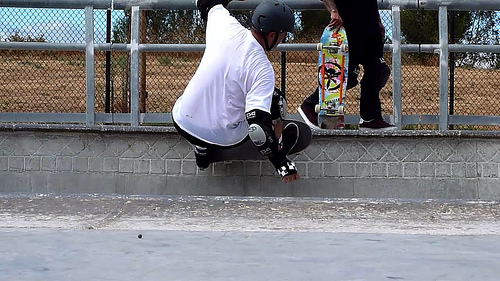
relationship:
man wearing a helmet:
[172, 0, 301, 183] [252, 0, 295, 51]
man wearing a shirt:
[172, 0, 301, 183] [172, 4, 275, 146]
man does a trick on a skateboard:
[172, 0, 301, 183] [209, 119, 312, 164]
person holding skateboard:
[297, 0, 391, 131] [314, 24, 349, 129]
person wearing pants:
[297, 0, 391, 131] [304, 29, 384, 118]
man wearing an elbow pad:
[172, 0, 301, 183] [245, 109, 279, 156]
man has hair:
[172, 0, 301, 183] [250, 26, 271, 38]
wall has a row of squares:
[0, 122, 500, 200] [0, 156, 500, 178]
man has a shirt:
[172, 0, 301, 183] [172, 4, 275, 146]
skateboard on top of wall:
[314, 24, 349, 129] [0, 122, 500, 200]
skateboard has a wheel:
[314, 24, 349, 129] [317, 42, 324, 50]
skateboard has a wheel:
[314, 24, 349, 129] [340, 44, 347, 53]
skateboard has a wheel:
[314, 24, 349, 129] [315, 104, 322, 113]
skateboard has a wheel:
[314, 24, 349, 129] [337, 105, 344, 113]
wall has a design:
[0, 122, 500, 200] [0, 133, 500, 177]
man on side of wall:
[172, 0, 301, 183] [0, 122, 500, 200]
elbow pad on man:
[245, 109, 279, 156] [172, 0, 301, 183]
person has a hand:
[297, 0, 391, 131] [328, 13, 343, 34]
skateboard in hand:
[314, 24, 349, 129] [328, 13, 343, 34]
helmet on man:
[252, 0, 295, 51] [172, 0, 301, 183]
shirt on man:
[172, 4, 275, 146] [172, 0, 301, 183]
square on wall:
[483, 162, 499, 177] [0, 122, 500, 200]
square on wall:
[466, 162, 482, 178] [0, 122, 500, 200]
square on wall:
[451, 162, 467, 178] [0, 122, 500, 200]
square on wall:
[419, 162, 436, 177] [0, 122, 500, 200]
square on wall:
[403, 162, 420, 177] [0, 122, 500, 200]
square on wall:
[387, 162, 404, 177] [0, 122, 500, 200]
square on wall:
[370, 162, 388, 177] [0, 122, 500, 200]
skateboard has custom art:
[314, 24, 349, 129] [318, 25, 349, 129]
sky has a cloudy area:
[0, 6, 500, 68] [0, 21, 106, 44]